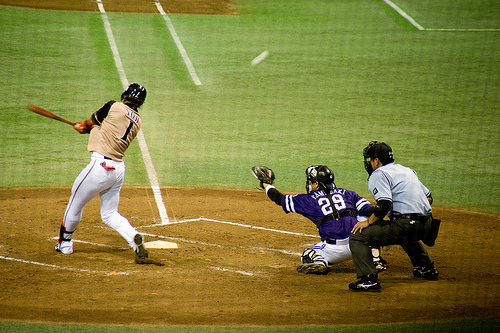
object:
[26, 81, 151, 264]
player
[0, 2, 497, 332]
field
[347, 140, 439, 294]
umpire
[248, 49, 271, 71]
baseball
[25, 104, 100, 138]
bat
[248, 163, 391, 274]
catcher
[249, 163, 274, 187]
mit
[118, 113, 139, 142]
player number